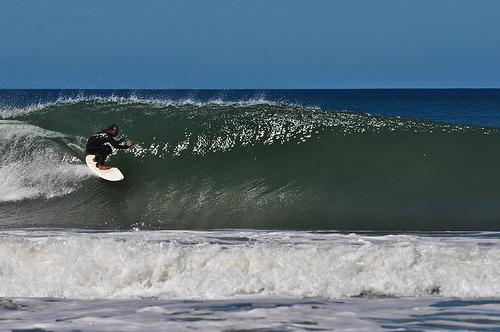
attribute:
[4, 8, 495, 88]
sky — blue, clear, cloudless, bright blue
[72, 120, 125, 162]
man — barefoot, crouched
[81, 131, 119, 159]
wetsuit — black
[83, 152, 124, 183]
surfboard — white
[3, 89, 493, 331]
water — foamy, rolling, frothy, white, bubbly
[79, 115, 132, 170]
surfer — crouched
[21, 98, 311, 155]
wave — dark, white, capped, sunlit, tall, green, foamy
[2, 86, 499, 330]
ocean — blue, calm